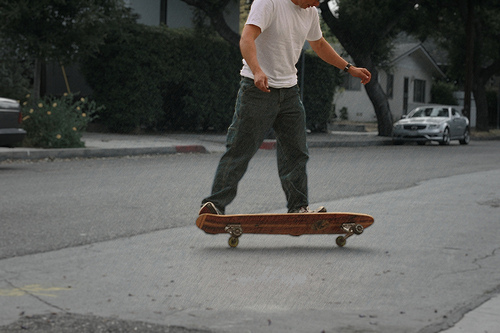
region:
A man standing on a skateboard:
[196, 2, 378, 244]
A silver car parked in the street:
[391, 102, 477, 151]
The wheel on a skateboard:
[348, 220, 365, 237]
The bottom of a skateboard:
[193, 207, 373, 239]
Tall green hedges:
[83, 29, 326, 131]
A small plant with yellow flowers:
[22, 90, 96, 148]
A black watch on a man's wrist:
[337, 56, 357, 75]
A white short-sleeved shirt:
[242, 0, 319, 82]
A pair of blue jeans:
[209, 70, 314, 208]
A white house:
[326, 42, 441, 137]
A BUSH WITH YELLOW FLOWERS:
[19, 90, 116, 154]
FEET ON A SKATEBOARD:
[186, 187, 376, 247]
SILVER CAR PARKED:
[393, 100, 477, 146]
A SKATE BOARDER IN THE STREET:
[199, 0, 398, 252]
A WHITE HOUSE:
[331, 39, 465, 141]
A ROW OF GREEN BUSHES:
[76, 13, 346, 138]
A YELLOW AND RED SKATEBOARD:
[193, 210, 373, 250]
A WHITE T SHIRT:
[219, 9, 385, 92]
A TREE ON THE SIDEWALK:
[316, 10, 431, 142]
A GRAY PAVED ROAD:
[359, 90, 499, 277]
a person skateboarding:
[182, 2, 460, 282]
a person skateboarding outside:
[199, 7, 402, 267]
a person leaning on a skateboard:
[192, 2, 449, 282]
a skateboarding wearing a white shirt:
[179, 2, 479, 285]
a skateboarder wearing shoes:
[154, 102, 414, 287]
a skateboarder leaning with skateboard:
[92, 121, 431, 286]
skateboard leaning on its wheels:
[152, 171, 439, 271]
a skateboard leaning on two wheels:
[172, 185, 421, 272]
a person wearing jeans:
[198, 12, 458, 301]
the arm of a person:
[236, 0, 273, 75]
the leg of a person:
[271, 100, 306, 210]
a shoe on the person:
[195, 195, 222, 215]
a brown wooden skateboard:
[191, 205, 376, 246]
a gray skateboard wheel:
[346, 220, 367, 235]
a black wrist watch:
[337, 55, 352, 70]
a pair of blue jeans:
[200, 80, 310, 210]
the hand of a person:
[248, 65, 270, 95]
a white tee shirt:
[236, 1, 326, 91]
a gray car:
[386, 99, 475, 158]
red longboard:
[204, 209, 374, 251]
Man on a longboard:
[199, 2, 369, 247]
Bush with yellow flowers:
[19, 94, 99, 149]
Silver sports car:
[392, 101, 474, 145]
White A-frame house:
[321, 35, 431, 120]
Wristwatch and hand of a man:
[340, 57, 371, 82]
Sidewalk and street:
[313, 143, 493, 203]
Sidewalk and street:
[5, 160, 190, 330]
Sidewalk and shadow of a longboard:
[175, 241, 495, 326]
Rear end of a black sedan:
[0, 95, 22, 151]